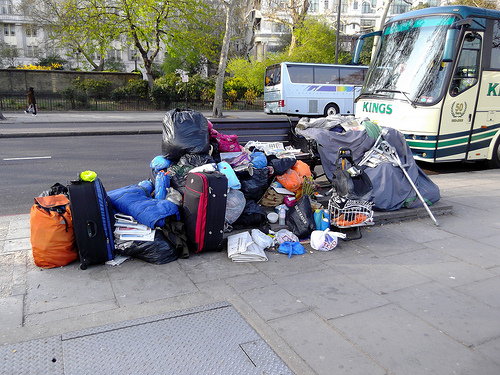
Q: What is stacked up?
A: Pile of stuff.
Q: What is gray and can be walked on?
A: The sidewalk.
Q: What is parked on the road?
A: Buses.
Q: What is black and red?
A: A suitcase.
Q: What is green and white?
A: The bus.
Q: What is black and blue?
A: The suitcase.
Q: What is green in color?
A: Trees.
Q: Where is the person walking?
A: On the sidewalk.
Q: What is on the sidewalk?
A: The bags and papers.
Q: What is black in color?
A: The suitcase.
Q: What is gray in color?
A: The street.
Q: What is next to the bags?
A: A bus.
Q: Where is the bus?
A: On the street.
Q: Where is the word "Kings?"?
A: On the bus.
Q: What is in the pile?
A: Luggage.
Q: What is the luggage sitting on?
A: On the sidewalk.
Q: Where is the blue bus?
A: Across the street.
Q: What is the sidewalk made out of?
A: Stone.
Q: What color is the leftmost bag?
A: Orange.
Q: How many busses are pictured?
A: 2.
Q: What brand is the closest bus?
A: Kings.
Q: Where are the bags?
A: On the sidewalk.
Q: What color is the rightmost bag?
A: Blue.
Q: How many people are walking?
A: 1.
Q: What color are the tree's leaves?
A: Green.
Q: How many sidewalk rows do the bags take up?
A: 8.